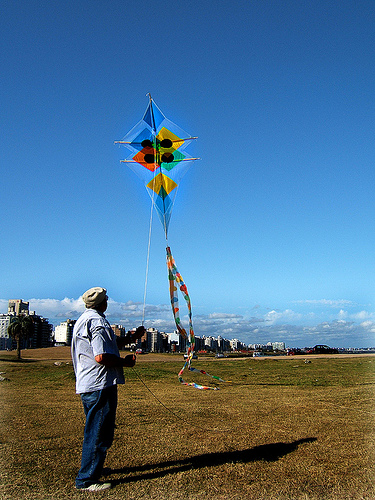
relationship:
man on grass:
[62, 287, 141, 495] [6, 344, 374, 497]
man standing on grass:
[62, 287, 141, 495] [6, 344, 374, 497]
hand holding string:
[125, 353, 139, 369] [131, 173, 271, 441]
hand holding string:
[133, 327, 147, 339] [131, 173, 271, 441]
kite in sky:
[112, 87, 230, 398] [13, 3, 374, 343]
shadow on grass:
[102, 423, 321, 491] [6, 344, 374, 497]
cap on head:
[82, 283, 109, 305] [82, 288, 109, 314]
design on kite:
[127, 95, 181, 233] [112, 87, 230, 398]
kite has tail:
[112, 87, 230, 398] [163, 241, 207, 403]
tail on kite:
[163, 241, 207, 403] [112, 87, 230, 398]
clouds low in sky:
[2, 293, 374, 339] [13, 3, 374, 343]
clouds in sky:
[2, 293, 374, 339] [13, 3, 374, 343]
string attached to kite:
[131, 173, 271, 441] [112, 87, 230, 398]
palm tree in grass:
[8, 315, 40, 363] [0, 352, 374, 500]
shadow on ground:
[102, 423, 321, 491] [2, 347, 374, 494]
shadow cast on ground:
[102, 423, 321, 491] [2, 347, 374, 494]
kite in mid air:
[112, 87, 230, 398] [5, 74, 373, 240]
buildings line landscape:
[51, 319, 295, 357] [5, 351, 372, 498]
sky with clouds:
[13, 3, 374, 343] [2, 293, 374, 339]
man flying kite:
[62, 287, 141, 495] [112, 87, 230, 398]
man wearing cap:
[62, 287, 141, 495] [82, 285, 109, 309]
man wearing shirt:
[62, 287, 141, 495] [67, 310, 126, 400]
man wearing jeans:
[62, 287, 141, 495] [78, 385, 123, 486]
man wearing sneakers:
[62, 287, 141, 495] [75, 464, 117, 494]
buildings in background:
[51, 319, 295, 357] [3, 1, 374, 359]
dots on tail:
[166, 248, 217, 390] [163, 241, 207, 403]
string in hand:
[131, 173, 271, 441] [125, 353, 139, 369]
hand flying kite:
[125, 353, 139, 369] [112, 87, 230, 398]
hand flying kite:
[133, 327, 147, 339] [112, 87, 230, 398]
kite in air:
[112, 87, 230, 398] [7, 1, 369, 341]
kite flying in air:
[112, 87, 230, 398] [7, 1, 369, 341]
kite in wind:
[112, 87, 230, 398] [2, 6, 373, 497]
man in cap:
[62, 287, 141, 495] [82, 285, 109, 309]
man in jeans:
[62, 287, 141, 495] [78, 385, 123, 486]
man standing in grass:
[62, 287, 141, 495] [0, 352, 374, 500]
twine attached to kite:
[131, 173, 271, 441] [112, 87, 230, 398]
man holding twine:
[62, 287, 141, 495] [131, 173, 271, 441]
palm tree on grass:
[8, 315, 40, 363] [0, 352, 374, 500]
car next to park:
[304, 340, 339, 355] [0, 310, 374, 498]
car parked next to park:
[304, 340, 339, 355] [0, 310, 374, 498]